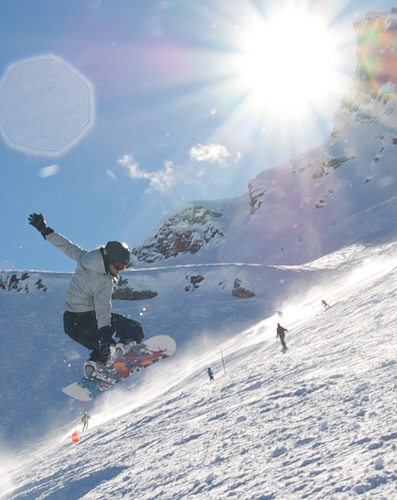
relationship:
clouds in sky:
[100, 115, 255, 209] [34, 13, 153, 98]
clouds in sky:
[100, 115, 255, 209] [2, 2, 381, 271]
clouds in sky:
[100, 115, 255, 209] [2, 3, 387, 242]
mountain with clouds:
[15, 132, 387, 307] [97, 95, 213, 182]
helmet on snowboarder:
[102, 221, 142, 264] [25, 223, 176, 385]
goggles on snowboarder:
[103, 248, 132, 281] [25, 223, 176, 385]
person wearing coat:
[29, 212, 144, 376] [47, 231, 116, 327]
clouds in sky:
[100, 115, 255, 209] [14, 10, 396, 298]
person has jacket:
[29, 212, 144, 376] [45, 231, 115, 327]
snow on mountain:
[4, 254, 391, 499] [126, 126, 375, 315]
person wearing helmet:
[29, 212, 144, 376] [103, 239, 131, 265]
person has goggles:
[29, 212, 144, 376] [108, 258, 131, 273]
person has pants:
[29, 212, 144, 376] [62, 311, 145, 357]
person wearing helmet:
[29, 212, 144, 376] [102, 242, 130, 259]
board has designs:
[56, 331, 187, 407] [73, 343, 167, 397]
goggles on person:
[111, 258, 129, 270] [29, 212, 144, 376]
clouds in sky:
[107, 149, 216, 188] [3, 10, 242, 215]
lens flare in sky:
[2, 53, 96, 157] [2, 2, 381, 271]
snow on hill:
[4, 254, 391, 499] [8, 260, 395, 498]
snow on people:
[181, 431, 227, 468] [271, 309, 286, 358]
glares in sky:
[192, 0, 397, 164] [2, 2, 381, 271]